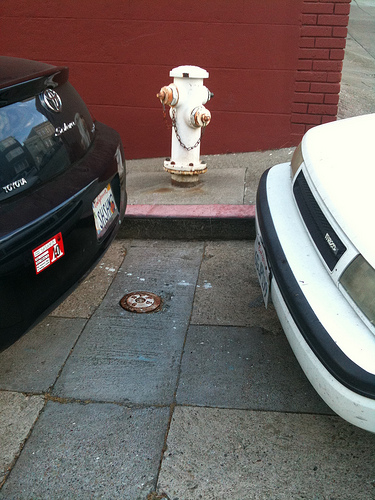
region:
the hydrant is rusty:
[157, 84, 177, 105]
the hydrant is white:
[180, 87, 194, 131]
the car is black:
[68, 116, 89, 136]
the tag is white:
[97, 200, 115, 216]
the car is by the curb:
[96, 197, 174, 237]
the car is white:
[318, 133, 343, 164]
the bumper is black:
[257, 207, 275, 235]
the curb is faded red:
[190, 205, 217, 215]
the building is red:
[230, 16, 250, 38]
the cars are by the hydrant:
[96, 119, 321, 212]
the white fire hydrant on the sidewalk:
[151, 58, 216, 187]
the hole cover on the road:
[114, 282, 168, 316]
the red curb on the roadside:
[132, 197, 253, 244]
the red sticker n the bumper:
[31, 231, 65, 273]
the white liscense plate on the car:
[92, 186, 120, 240]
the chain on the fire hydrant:
[160, 103, 192, 148]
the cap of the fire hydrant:
[154, 84, 172, 107]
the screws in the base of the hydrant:
[165, 155, 205, 172]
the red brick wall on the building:
[302, 1, 348, 119]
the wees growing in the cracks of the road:
[40, 385, 178, 498]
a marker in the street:
[118, 286, 162, 312]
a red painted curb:
[121, 195, 264, 244]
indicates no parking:
[117, 199, 257, 242]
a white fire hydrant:
[153, 61, 217, 192]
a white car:
[247, 119, 374, 440]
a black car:
[0, 52, 131, 351]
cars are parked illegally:
[1, 51, 374, 443]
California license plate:
[85, 181, 126, 241]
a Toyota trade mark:
[2, 177, 30, 195]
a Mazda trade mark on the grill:
[321, 232, 339, 255]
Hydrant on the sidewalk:
[153, 60, 214, 187]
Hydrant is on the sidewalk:
[153, 56, 214, 186]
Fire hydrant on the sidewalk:
[155, 60, 215, 186]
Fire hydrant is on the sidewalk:
[155, 58, 219, 189]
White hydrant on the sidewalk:
[153, 61, 223, 190]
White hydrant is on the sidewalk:
[153, 58, 220, 188]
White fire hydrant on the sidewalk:
[152, 62, 218, 187]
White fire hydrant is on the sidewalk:
[154, 60, 222, 188]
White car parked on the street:
[248, 105, 374, 439]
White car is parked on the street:
[250, 103, 372, 437]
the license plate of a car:
[89, 181, 119, 242]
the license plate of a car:
[251, 235, 271, 310]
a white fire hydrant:
[156, 62, 213, 187]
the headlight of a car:
[289, 139, 304, 179]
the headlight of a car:
[337, 246, 373, 327]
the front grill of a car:
[290, 169, 346, 277]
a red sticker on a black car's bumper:
[30, 230, 72, 275]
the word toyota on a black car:
[0, 177, 31, 194]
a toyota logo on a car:
[39, 85, 66, 114]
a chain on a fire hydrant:
[172, 105, 207, 151]